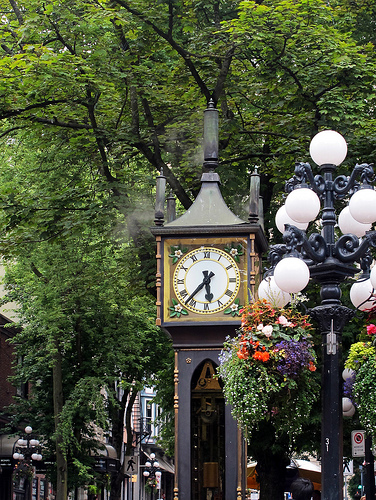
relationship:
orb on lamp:
[308, 124, 351, 169] [256, 126, 373, 496]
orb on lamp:
[286, 187, 322, 223] [256, 126, 373, 496]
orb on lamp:
[348, 187, 375, 228] [256, 126, 373, 496]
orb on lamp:
[272, 255, 310, 293] [256, 126, 373, 496]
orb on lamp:
[349, 276, 375, 310] [256, 126, 373, 496]